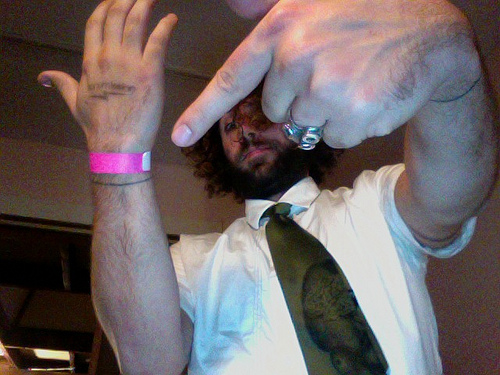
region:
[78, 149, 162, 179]
a pink wrist band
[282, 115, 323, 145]
a metal ring on a finger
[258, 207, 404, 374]
an olive green tie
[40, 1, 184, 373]
a mans hairy arm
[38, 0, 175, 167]
a pink wristband on a mans wrist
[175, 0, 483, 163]
a man pointing with his index finger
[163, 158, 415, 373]
a white button down shirt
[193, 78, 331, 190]
a man with a shaggy head of hair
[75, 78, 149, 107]
a black hand tattoo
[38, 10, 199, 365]
a man's hairy arm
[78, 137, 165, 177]
The bracelet is pink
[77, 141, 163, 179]
he has a pink wristband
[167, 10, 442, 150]
pointing at the wristband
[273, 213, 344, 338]
his tie is green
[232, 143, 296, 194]
He has a large beard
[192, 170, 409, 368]
his shirt is white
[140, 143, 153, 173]
white part of the band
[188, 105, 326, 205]
his hair is curly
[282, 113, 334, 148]
He is wearing a ring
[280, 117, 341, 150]
the ring is silver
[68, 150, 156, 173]
pink and white band on the wrist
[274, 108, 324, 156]
ring in the finger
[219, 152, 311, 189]
man with a beard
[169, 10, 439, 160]
finger pointing to the pink and white band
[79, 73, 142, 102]
black stamp on the back of the hand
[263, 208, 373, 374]
green tie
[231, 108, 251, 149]
hair hanging in front of the man's face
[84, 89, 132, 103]
lightning bold stamp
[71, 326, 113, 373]
door behind the man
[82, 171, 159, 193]
black line around the man's wrist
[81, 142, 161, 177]
Man wearing a wrist band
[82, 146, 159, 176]
Man is wearing a wrist band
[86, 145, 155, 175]
Man wearing a pink wrist band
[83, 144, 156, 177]
Man is wearing a pink wrist band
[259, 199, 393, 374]
Man wearing a tie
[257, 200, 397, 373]
Man is wearing a tie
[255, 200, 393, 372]
Man wearing a green black tie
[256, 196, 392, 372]
Man is wearing a green and black tie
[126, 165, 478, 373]
Man wearing a white shirt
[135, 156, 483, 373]
Man is wearing a white shirt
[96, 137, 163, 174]
Man is wearing a pink band around wrist.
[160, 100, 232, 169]
Man is pointing at his wrist.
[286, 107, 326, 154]
The man is wearing ring on finger.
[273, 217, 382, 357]
the man is wearing green tie.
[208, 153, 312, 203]
The man has a beard.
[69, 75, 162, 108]
A tattoo on the man's hand.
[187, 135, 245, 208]
The man has brown curly hair.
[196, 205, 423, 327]
The man is wearing a white shirt.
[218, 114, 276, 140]
The person is wearing glasses.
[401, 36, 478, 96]
Hair on the man hand.